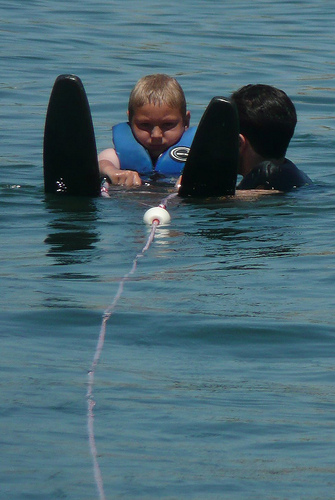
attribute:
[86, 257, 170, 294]
rope — connected to boat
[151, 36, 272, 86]
water — calm, wide, black, blue, in lake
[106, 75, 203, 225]
boy — blonde, learning water skiin, hanging on, water skiing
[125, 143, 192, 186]
life vest — blue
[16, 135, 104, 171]
skis — black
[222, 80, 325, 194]
person — instructor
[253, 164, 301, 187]
black top — life vest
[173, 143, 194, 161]
logo — black, gray, white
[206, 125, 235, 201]
water ski — paired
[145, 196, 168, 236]
buoy — white